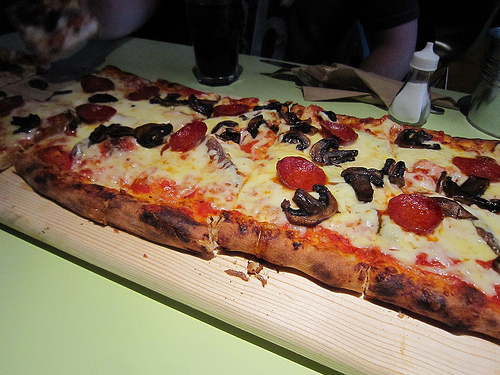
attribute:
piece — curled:
[270, 147, 336, 190]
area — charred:
[134, 199, 209, 238]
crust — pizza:
[22, 143, 499, 352]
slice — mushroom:
[274, 181, 346, 230]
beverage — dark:
[192, 17, 235, 67]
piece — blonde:
[2, 160, 498, 372]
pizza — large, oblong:
[7, 54, 498, 344]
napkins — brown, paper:
[257, 51, 471, 134]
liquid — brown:
[199, 45, 234, 73]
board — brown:
[2, 59, 499, 366]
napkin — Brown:
[274, 48, 394, 116]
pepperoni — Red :
[266, 153, 327, 191]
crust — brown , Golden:
[84, 206, 484, 294]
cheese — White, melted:
[110, 142, 425, 251]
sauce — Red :
[150, 196, 385, 285]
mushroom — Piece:
[272, 189, 351, 228]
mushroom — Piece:
[292, 184, 342, 230]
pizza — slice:
[249, 156, 368, 288]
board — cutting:
[18, 175, 448, 373]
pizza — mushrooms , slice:
[50, 63, 484, 323]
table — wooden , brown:
[57, 35, 476, 372]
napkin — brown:
[296, 65, 399, 114]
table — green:
[0, 38, 477, 368]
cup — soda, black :
[169, 20, 245, 85]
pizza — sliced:
[42, 95, 464, 304]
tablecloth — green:
[7, 245, 268, 373]